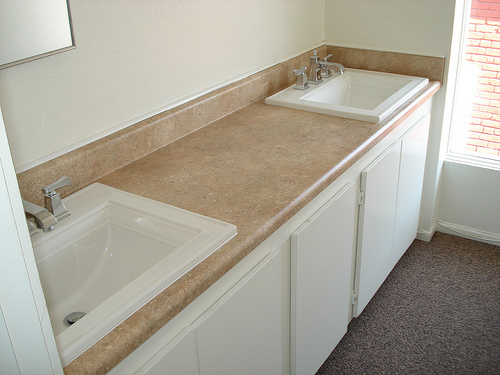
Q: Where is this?
A: This is at the bathroom.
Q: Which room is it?
A: It is a bathroom.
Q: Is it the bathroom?
A: Yes, it is the bathroom.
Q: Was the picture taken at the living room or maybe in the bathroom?
A: It was taken at the bathroom.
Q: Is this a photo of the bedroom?
A: No, the picture is showing the bathroom.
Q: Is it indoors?
A: Yes, it is indoors.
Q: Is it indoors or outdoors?
A: It is indoors.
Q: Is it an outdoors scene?
A: No, it is indoors.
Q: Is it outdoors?
A: No, it is indoors.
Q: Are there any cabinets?
A: Yes, there is a cabinet.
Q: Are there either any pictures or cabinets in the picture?
A: Yes, there is a cabinet.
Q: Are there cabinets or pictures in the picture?
A: Yes, there is a cabinet.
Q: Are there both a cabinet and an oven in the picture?
A: No, there is a cabinet but no ovens.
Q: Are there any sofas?
A: No, there are no sofas.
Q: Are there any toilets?
A: No, there are no toilets.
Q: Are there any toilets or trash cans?
A: No, there are no toilets or trash cans.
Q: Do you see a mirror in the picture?
A: Yes, there is a mirror.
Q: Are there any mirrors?
A: Yes, there is a mirror.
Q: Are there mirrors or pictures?
A: Yes, there is a mirror.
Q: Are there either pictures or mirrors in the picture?
A: Yes, there is a mirror.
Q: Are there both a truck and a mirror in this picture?
A: No, there is a mirror but no trucks.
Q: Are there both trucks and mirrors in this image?
A: No, there is a mirror but no trucks.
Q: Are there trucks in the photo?
A: No, there are no trucks.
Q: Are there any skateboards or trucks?
A: No, there are no trucks or skateboards.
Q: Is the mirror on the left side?
A: Yes, the mirror is on the left of the image.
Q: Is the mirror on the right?
A: No, the mirror is on the left of the image.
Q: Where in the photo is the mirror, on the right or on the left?
A: The mirror is on the left of the image.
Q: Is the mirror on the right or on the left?
A: The mirror is on the left of the image.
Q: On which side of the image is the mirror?
A: The mirror is on the left of the image.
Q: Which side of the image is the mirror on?
A: The mirror is on the left of the image.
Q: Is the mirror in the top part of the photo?
A: Yes, the mirror is in the top of the image.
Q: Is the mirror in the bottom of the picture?
A: No, the mirror is in the top of the image.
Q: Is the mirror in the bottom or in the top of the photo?
A: The mirror is in the top of the image.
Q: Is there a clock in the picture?
A: No, there are no clocks.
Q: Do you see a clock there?
A: No, there are no clocks.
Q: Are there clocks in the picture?
A: No, there are no clocks.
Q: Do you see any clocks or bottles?
A: No, there are no clocks or bottles.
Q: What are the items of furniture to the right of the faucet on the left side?
A: The pieces of furniture are cabinets.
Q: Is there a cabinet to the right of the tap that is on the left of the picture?
A: Yes, there are cabinets to the right of the tap.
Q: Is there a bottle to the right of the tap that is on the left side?
A: No, there are cabinets to the right of the tap.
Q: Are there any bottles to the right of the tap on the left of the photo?
A: No, there are cabinets to the right of the tap.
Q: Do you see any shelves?
A: No, there are no shelves.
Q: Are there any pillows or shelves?
A: No, there are no shelves or pillows.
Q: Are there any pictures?
A: No, there are no pictures.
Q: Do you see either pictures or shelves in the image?
A: No, there are no pictures or shelves.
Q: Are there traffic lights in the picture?
A: No, there are no traffic lights.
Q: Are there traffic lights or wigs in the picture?
A: No, there are no traffic lights or wigs.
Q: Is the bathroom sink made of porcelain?
A: Yes, the sink is made of porcelain.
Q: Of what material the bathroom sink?
A: The sink is made of porcelain.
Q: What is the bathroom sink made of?
A: The sink is made of porcelain.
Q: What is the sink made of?
A: The sink is made of porcelain.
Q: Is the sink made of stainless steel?
A: No, the sink is made of porcelain.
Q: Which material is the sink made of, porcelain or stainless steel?
A: The sink is made of porcelain.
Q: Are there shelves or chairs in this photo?
A: No, there are no shelves or chairs.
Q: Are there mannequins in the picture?
A: No, there are no mannequins.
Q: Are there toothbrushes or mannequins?
A: No, there are no mannequins or toothbrushes.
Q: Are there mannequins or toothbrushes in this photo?
A: No, there are no mannequins or toothbrushes.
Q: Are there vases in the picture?
A: No, there are no vases.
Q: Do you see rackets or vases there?
A: No, there are no vases or rackets.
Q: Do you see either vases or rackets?
A: No, there are no vases or rackets.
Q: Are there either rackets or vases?
A: No, there are no vases or rackets.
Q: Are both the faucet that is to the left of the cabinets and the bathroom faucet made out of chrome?
A: Yes, both the faucet and the tap are made of chrome.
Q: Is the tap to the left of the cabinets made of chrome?
A: Yes, the faucet is made of chrome.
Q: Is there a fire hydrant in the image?
A: No, there are no fire hydrants.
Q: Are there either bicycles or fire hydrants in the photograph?
A: No, there are no fire hydrants or bicycles.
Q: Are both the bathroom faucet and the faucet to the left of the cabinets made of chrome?
A: Yes, both the tap and the tap are made of chrome.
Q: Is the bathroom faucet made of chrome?
A: Yes, the tap is made of chrome.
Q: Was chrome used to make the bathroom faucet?
A: Yes, the tap is made of chrome.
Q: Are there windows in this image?
A: Yes, there is a window.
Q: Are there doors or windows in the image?
A: Yes, there is a window.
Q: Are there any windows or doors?
A: Yes, there is a window.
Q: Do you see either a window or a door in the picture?
A: Yes, there is a window.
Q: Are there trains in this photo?
A: No, there are no trains.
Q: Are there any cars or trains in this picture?
A: No, there are no trains or cars.